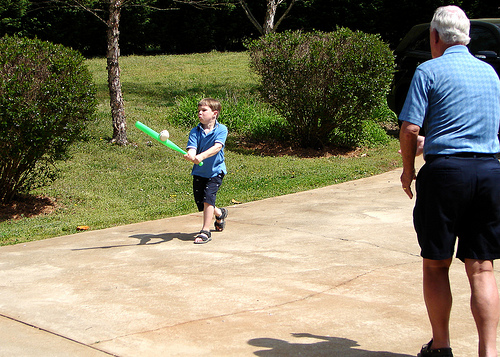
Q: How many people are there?
A: Two.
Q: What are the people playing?
A: Ball.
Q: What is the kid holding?
A: Bat.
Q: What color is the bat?
A: Green.